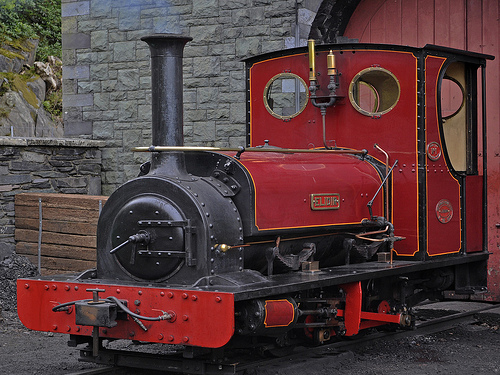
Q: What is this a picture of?
A: A Train.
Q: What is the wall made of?
A: Stone.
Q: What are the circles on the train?
A: Windows.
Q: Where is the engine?
A: Front of the train.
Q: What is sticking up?
A: Black smoke stack.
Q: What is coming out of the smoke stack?
A: Smoke.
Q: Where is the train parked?
A: On the track.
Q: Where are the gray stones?
A: On the building.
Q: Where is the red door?
A: Behind the train.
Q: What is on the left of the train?
A: Ties.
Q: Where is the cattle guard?
A: The red port on the front of the train.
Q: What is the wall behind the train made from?
A: Grey bricks.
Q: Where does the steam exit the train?
A: The smokestack.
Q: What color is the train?
A: Red.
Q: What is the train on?
A: Train tracks.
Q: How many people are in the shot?
A: 0.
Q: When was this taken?
A: Daytime.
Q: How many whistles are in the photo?
A: 2.